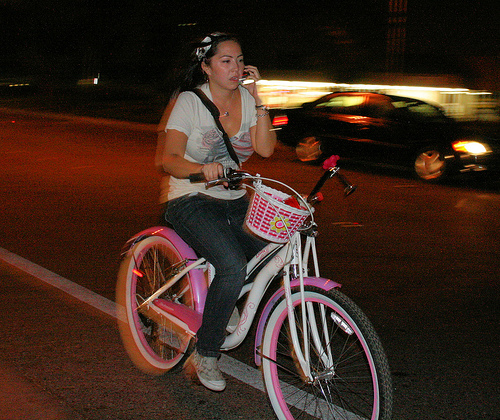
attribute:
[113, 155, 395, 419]
bike — pink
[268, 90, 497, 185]
car — black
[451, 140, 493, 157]
headlight — on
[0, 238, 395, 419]
line — white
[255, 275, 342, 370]
fender — pink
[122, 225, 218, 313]
fender — pink